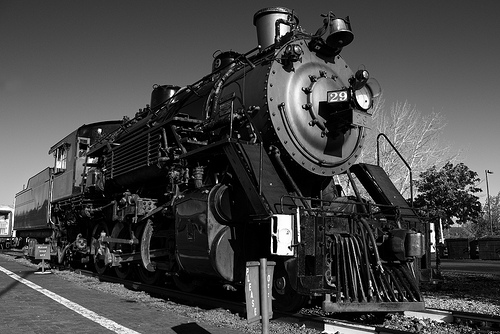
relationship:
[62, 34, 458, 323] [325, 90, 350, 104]
train has 29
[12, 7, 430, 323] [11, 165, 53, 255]
train has caboose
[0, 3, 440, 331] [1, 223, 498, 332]
locomotive on railroad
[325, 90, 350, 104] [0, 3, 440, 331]
29 in front of locomotive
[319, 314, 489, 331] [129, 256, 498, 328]
gravel on railroad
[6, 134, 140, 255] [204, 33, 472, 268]
cars behind engine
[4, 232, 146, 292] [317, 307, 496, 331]
wheels on rail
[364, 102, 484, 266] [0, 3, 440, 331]
trees on right side of locomotive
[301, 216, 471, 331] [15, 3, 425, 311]
cow catcher of train engine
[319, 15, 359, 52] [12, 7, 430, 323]
bell in front of train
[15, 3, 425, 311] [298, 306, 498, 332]
train engine on tracks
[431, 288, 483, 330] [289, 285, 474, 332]
gravel next to tracks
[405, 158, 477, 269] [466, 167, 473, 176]
tree with leaf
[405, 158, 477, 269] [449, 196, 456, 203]
tree with leaf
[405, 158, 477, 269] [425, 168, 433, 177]
tree with leaf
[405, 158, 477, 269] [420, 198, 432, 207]
tree with leaf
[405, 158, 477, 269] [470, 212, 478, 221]
tree with leaf